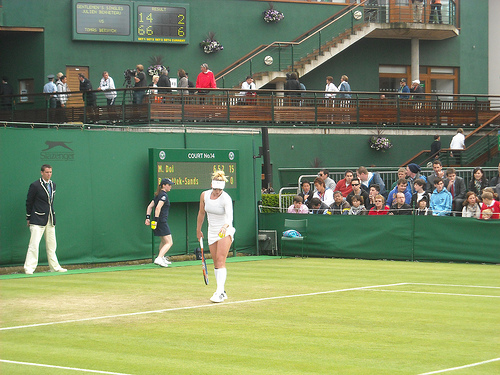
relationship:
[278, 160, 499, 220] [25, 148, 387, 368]
spectators in match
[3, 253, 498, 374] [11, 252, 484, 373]
grass on court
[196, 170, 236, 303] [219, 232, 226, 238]
female player bounce ball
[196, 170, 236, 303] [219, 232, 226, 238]
female player plays ball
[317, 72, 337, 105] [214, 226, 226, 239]
woman has hand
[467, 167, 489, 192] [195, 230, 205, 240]
woman has hand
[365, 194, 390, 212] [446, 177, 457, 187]
woman has hand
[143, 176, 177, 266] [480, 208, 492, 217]
woman has hand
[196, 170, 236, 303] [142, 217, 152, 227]
female player has hand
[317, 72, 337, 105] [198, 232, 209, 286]
woman has racket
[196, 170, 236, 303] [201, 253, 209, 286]
female player has racket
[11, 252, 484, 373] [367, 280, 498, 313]
court has stripe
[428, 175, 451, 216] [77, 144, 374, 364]
person watch tennis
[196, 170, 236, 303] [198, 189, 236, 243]
female player wears clothes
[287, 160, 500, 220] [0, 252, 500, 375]
spectators side court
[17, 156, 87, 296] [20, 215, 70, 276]
man wears white pants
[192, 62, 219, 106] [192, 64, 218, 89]
man wears top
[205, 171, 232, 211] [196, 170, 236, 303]
head of female player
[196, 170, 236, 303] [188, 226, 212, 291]
female player holds racket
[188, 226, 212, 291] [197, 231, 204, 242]
racket in hand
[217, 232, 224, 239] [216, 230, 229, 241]
ball in hand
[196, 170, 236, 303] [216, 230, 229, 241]
female player has hand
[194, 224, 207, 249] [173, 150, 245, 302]
hand of woman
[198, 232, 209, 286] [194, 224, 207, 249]
racket in hand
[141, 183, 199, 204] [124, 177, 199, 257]
hat on woman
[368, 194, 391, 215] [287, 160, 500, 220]
woman in spectators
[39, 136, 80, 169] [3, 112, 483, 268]
logo on wall